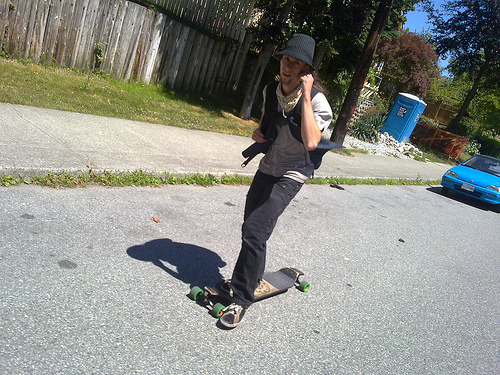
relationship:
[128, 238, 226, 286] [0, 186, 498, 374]
shadow on pavement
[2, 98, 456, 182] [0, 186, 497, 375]
sidewalk near pavement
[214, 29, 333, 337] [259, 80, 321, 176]
man has vest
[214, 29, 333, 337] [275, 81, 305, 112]
man has scarf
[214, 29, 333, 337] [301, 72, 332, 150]
man has arm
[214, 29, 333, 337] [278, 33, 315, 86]
man has head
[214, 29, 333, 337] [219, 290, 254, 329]
man has foot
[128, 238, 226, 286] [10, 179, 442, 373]
shadow on ground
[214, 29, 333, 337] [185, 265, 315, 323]
man on skateboard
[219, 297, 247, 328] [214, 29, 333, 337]
shoe of man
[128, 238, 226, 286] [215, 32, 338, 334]
shadow made by skater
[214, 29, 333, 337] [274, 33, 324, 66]
man wearing fedora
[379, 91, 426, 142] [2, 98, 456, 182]
port a potty along sidewalk